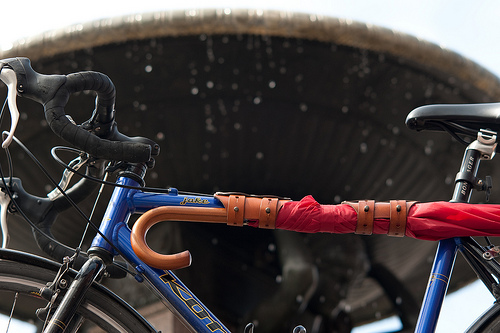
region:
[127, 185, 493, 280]
a red umbrella on a bike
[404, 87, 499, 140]
the seat of a bike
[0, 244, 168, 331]
the wheel of a bike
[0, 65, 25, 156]
the handbreak of a bike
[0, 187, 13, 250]
the handbreak of a bike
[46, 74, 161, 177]
the handle of a bike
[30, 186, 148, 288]
the handle of a bike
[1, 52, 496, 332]
a blue bike with a red umbrella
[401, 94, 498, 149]
a black seat on a bike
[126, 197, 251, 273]
the wooden handle of an umbrella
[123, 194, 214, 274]
handle of a umbrella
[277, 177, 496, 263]
top of a an umbrella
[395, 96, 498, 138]
seat of a bicycle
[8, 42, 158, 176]
handlebar of a bicycle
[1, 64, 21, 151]
brake on a bicycle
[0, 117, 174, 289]
brake wires on a bicycle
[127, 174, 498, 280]
umbrella attached to a bicycle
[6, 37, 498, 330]
a blue bicycle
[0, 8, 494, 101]
archway of a tunnel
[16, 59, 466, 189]
a dark tunnel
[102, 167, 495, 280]
umbrella strapped to the bike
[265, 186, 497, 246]
red cloth of the umbrella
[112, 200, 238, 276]
umbrella handle is brown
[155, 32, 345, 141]
rain is falling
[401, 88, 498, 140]
black bike seat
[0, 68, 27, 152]
silver brake handle on the bike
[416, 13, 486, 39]
sky appears to be white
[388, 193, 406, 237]
straps are brown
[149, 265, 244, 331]
black letters on the bike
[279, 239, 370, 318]
statue of person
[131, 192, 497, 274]
an umbrella strapped to a bicycle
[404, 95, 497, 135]
the seat of a bicycle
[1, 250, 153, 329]
the wheel of a bicycle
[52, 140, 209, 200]
the brake line of a bicycle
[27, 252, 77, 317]
the brake on the front of a bicycle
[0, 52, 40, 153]
the brake handle on the handle bar of a bicycle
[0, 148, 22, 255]
the brake handle on the handle bar of a bicycle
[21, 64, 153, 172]
the handle bar of a bicycle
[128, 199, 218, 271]
the handle of an umbrells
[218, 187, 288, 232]
the strap to hold an umbrella on a bicycle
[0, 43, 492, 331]
shiny blue metallic bicycle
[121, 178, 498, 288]
closed red umbrella with brown handle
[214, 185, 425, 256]
adjustable brown leather straps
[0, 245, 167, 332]
matte black rubber bicycle tire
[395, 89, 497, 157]
shiny black bicycle seat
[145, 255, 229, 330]
yellow outlined black lettering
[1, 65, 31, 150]
silver metal bicycle brake handles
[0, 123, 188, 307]
thin black bicycle brake lines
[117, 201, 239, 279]
light brown umbrella handle